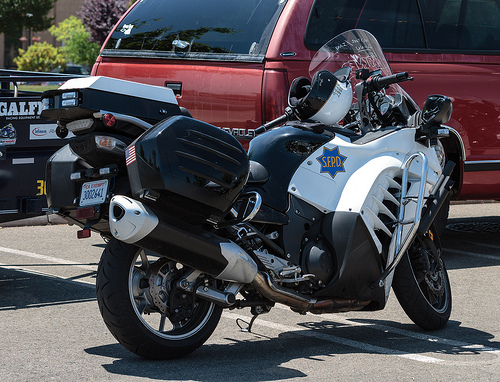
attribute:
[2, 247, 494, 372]
line — white